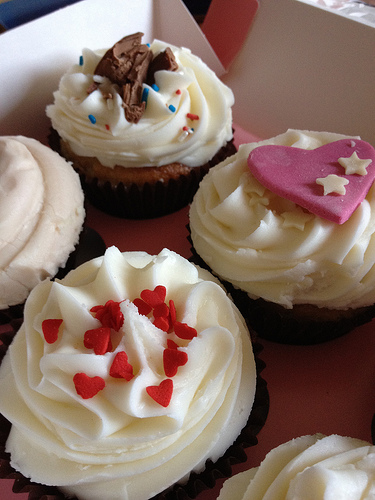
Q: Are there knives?
A: No, there are no knives.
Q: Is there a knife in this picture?
A: No, there are no knives.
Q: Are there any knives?
A: No, there are no knives.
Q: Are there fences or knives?
A: No, there are no knives or fences.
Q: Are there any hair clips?
A: No, there are no hair clips.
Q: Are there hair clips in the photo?
A: No, there are no hair clips.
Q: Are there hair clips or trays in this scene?
A: No, there are no hair clips or trays.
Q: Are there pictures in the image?
A: No, there are no pictures.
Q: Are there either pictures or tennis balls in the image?
A: No, there are no pictures or tennis balls.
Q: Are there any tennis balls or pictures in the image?
A: No, there are no pictures or tennis balls.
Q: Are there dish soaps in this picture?
A: No, there are no dish soaps.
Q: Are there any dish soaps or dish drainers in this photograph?
A: No, there are no dish soaps or dish drainers.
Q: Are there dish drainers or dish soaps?
A: No, there are no dish soaps or dish drainers.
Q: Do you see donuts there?
A: No, there are no donuts.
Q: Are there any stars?
A: Yes, there is a star.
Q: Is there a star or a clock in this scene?
A: Yes, there is a star.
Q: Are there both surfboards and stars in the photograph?
A: No, there is a star but no surfboards.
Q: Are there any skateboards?
A: No, there are no skateboards.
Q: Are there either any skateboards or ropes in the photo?
A: No, there are no skateboards or ropes.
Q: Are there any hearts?
A: Yes, there is a heart.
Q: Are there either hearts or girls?
A: Yes, there is a heart.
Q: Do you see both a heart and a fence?
A: No, there is a heart but no fences.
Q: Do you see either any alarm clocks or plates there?
A: No, there are no plates or alarm clocks.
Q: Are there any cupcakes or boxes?
A: Yes, there is a cupcake.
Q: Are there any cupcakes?
A: Yes, there is a cupcake.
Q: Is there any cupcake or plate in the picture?
A: Yes, there is a cupcake.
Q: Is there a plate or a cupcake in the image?
A: Yes, there is a cupcake.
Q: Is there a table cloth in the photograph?
A: No, there are no tablecloths.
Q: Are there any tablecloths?
A: No, there are no tablecloths.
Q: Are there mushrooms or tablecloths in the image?
A: No, there are no tablecloths or mushrooms.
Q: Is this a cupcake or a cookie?
A: This is a cupcake.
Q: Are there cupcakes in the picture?
A: Yes, there is a cupcake.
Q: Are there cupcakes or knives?
A: Yes, there is a cupcake.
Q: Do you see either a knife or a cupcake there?
A: Yes, there is a cupcake.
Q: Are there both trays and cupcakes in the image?
A: No, there is a cupcake but no trays.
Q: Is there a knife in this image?
A: No, there are no knives.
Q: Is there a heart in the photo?
A: Yes, there is a heart.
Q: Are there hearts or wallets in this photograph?
A: Yes, there is a heart.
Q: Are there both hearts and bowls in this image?
A: No, there is a heart but no bowls.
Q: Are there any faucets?
A: No, there are no faucets.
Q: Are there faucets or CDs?
A: No, there are no faucets or cds.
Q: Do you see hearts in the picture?
A: Yes, there is a heart.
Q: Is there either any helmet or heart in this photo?
A: Yes, there is a heart.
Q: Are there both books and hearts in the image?
A: No, there is a heart but no books.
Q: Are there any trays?
A: No, there are no trays.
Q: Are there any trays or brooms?
A: No, there are no trays or brooms.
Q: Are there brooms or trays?
A: No, there are no trays or brooms.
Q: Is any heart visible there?
A: Yes, there is a heart.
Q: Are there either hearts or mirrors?
A: Yes, there is a heart.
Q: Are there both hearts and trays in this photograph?
A: No, there is a heart but no trays.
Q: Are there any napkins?
A: No, there are no napkins.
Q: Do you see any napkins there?
A: No, there are no napkins.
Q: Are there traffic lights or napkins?
A: No, there are no napkins or traffic lights.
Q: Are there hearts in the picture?
A: Yes, there is a heart.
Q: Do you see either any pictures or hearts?
A: Yes, there is a heart.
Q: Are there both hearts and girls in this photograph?
A: No, there is a heart but no girls.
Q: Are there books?
A: No, there are no books.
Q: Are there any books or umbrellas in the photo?
A: No, there are no books or umbrellas.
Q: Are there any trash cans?
A: No, there are no trash cans.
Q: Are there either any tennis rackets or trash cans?
A: No, there are no trash cans or tennis rackets.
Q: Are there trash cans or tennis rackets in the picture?
A: No, there are no trash cans or tennis rackets.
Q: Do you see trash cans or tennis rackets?
A: No, there are no trash cans or tennis rackets.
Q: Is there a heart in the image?
A: Yes, there is a heart.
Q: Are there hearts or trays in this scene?
A: Yes, there is a heart.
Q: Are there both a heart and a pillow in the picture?
A: No, there is a heart but no pillows.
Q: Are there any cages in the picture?
A: No, there are no cages.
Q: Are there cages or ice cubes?
A: No, there are no cages or ice cubes.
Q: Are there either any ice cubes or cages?
A: No, there are no cages or ice cubes.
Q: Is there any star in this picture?
A: Yes, there is a star.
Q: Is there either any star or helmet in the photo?
A: Yes, there is a star.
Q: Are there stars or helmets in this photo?
A: Yes, there is a star.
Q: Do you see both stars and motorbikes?
A: No, there is a star but no motorcycles.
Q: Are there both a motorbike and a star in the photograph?
A: No, there is a star but no motorcycles.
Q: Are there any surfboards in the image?
A: No, there are no surfboards.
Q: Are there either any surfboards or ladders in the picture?
A: No, there are no surfboards or ladders.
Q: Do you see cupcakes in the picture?
A: Yes, there is a cupcake.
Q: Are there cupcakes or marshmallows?
A: Yes, there is a cupcake.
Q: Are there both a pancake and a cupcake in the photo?
A: No, there is a cupcake but no pancakes.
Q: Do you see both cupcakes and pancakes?
A: No, there is a cupcake but no pancakes.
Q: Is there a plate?
A: No, there are no plates.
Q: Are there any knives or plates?
A: No, there are no plates or knives.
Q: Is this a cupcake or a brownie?
A: This is a cupcake.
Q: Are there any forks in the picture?
A: No, there are no forks.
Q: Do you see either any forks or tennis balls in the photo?
A: No, there are no forks or tennis balls.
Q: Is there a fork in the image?
A: No, there are no forks.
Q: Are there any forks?
A: No, there are no forks.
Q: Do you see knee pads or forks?
A: No, there are no forks or knee pads.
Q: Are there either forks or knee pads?
A: No, there are no forks or knee pads.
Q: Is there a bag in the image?
A: No, there are no bags.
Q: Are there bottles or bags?
A: No, there are no bags or bottles.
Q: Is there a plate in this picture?
A: No, there are no plates.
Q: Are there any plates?
A: No, there are no plates.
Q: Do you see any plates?
A: No, there are no plates.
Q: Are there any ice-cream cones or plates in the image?
A: No, there are no plates or ice-cream cones.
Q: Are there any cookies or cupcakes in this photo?
A: Yes, there is a cupcake.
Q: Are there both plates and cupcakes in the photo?
A: No, there is a cupcake but no plates.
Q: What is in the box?
A: The cupcake is in the box.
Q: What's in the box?
A: The cupcake is in the box.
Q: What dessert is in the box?
A: The dessert is a cupcake.